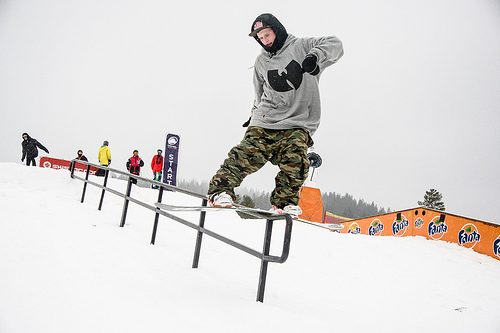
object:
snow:
[354, 232, 429, 268]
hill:
[0, 152, 262, 239]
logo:
[425, 213, 450, 241]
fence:
[348, 202, 499, 261]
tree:
[417, 186, 445, 211]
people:
[17, 132, 51, 167]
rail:
[64, 156, 307, 304]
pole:
[248, 253, 273, 307]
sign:
[165, 130, 179, 191]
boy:
[204, 11, 346, 215]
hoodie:
[242, 13, 344, 137]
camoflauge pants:
[207, 116, 313, 208]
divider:
[415, 199, 496, 250]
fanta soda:
[451, 219, 484, 250]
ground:
[330, 293, 499, 326]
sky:
[354, 8, 484, 61]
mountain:
[157, 176, 411, 250]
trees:
[171, 170, 410, 225]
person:
[94, 139, 114, 178]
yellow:
[97, 147, 110, 166]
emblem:
[262, 57, 303, 93]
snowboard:
[153, 201, 344, 232]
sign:
[390, 213, 411, 238]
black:
[24, 139, 35, 160]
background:
[191, 136, 372, 196]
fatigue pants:
[207, 126, 318, 210]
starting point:
[164, 132, 180, 189]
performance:
[148, 10, 397, 260]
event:
[19, 101, 490, 290]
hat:
[246, 12, 292, 53]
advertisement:
[379, 208, 499, 257]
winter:
[303, 218, 423, 313]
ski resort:
[0, 107, 499, 332]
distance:
[183, 111, 237, 127]